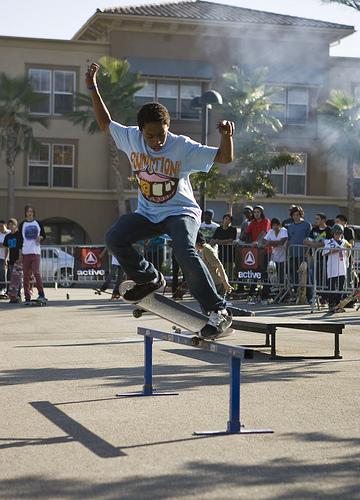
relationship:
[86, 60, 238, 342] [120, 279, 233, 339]
boy on skateboard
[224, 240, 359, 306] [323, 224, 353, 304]
fence in front of boy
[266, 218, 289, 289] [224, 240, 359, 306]
person on fence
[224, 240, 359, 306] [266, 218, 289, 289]
fence next to person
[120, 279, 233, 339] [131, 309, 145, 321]
skateboard has wheel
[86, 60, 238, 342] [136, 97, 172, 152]
boy has head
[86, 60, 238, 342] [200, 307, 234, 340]
boy wearing shoe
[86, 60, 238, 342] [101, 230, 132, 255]
boy has knee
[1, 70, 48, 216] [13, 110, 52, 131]
tree has leaves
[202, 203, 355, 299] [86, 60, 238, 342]
crowd watching boy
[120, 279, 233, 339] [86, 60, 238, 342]
skateboard underneath boy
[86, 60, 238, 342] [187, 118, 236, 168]
boy has left arm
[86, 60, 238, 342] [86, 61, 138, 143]
boy has right arm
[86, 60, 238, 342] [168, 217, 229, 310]
boy has left leg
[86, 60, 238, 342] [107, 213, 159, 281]
boy has right leg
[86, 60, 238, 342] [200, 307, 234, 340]
boy has shoe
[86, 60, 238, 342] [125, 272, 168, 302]
boy has shoe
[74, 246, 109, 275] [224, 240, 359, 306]
advertisement on fence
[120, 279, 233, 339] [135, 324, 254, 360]
skateboard on rail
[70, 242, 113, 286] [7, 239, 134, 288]
advertisement on fence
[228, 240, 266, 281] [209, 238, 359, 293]
sign on wall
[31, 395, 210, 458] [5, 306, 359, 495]
shadow on court